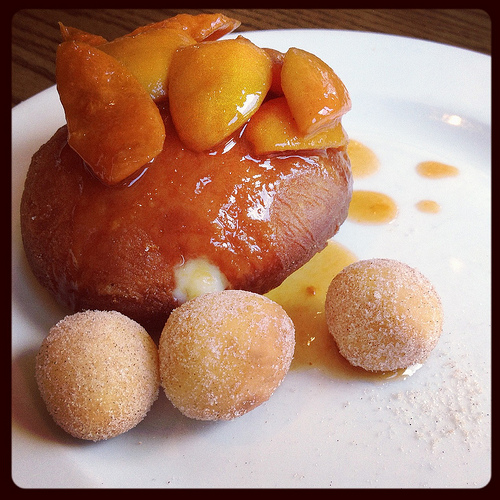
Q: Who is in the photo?
A: No one.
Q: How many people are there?
A: None.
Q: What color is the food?
A: Brown and yellow.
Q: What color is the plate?
A: White.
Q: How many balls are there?
A: Three.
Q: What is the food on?
A: A plate.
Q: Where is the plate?
A: Below the food.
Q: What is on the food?
A: Sauce.